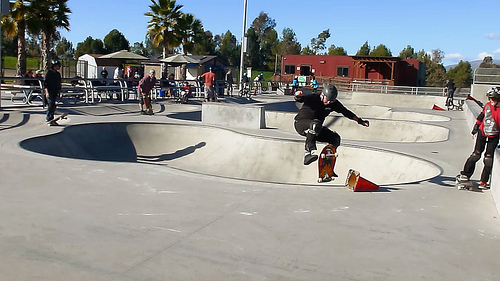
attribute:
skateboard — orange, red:
[315, 143, 344, 189]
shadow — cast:
[134, 139, 208, 166]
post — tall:
[233, 0, 257, 96]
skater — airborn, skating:
[290, 83, 374, 170]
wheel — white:
[335, 150, 340, 160]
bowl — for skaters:
[20, 120, 456, 199]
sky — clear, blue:
[1, 0, 497, 69]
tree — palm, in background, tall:
[139, 1, 196, 90]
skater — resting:
[37, 57, 75, 129]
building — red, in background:
[268, 47, 427, 94]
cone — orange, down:
[343, 167, 389, 192]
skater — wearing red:
[447, 75, 500, 191]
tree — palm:
[20, 2, 73, 91]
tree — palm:
[1, 0, 32, 76]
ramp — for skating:
[195, 96, 273, 130]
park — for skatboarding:
[0, 67, 498, 279]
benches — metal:
[0, 77, 265, 112]